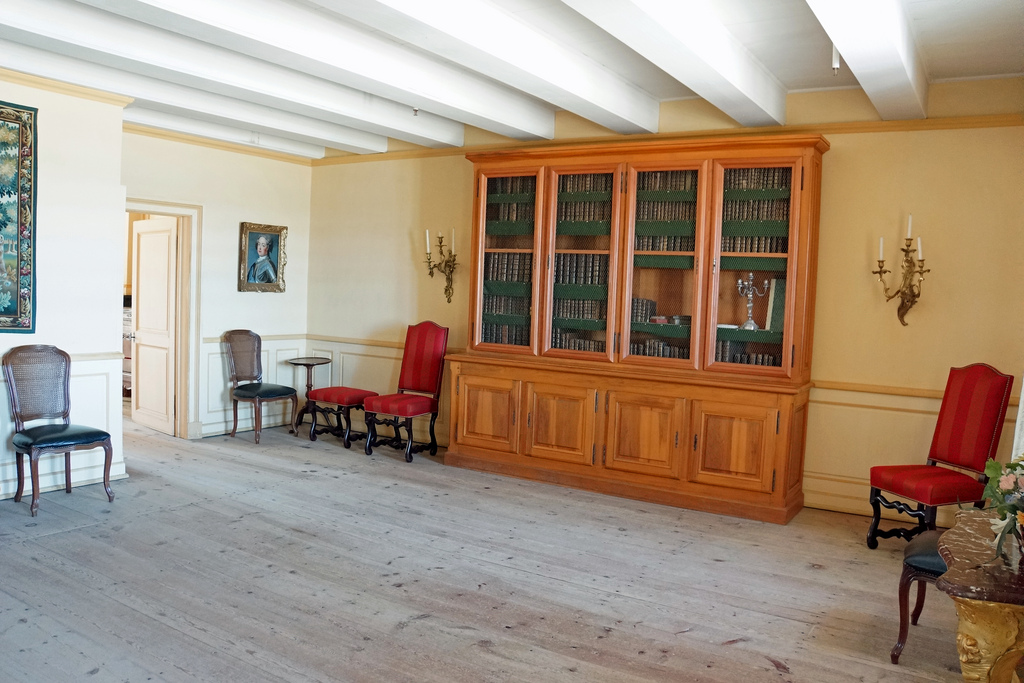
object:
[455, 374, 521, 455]
door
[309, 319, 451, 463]
stool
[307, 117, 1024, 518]
wainscoating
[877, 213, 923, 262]
candles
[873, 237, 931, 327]
sconce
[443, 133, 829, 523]
bookcase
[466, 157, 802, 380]
doors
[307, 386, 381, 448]
ottoman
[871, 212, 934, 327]
candle holder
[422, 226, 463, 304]
candle holder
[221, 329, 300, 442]
chair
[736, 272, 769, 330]
candelabra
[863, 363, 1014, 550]
chair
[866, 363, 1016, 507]
cushions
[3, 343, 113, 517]
chair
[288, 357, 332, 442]
table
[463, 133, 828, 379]
cabinet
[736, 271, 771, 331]
holder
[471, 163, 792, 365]
book case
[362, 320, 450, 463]
chair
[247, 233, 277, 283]
man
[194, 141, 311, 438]
wall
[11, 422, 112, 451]
seat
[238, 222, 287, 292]
frame